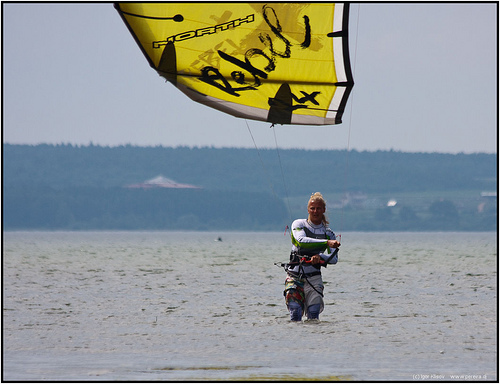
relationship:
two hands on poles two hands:
[285, 219, 336, 265] [286, 229, 342, 264]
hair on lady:
[307, 191, 331, 231] [277, 179, 345, 318]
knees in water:
[282, 300, 326, 321] [4, 220, 480, 381]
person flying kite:
[272, 186, 351, 321] [106, 6, 367, 127]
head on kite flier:
[305, 189, 331, 227] [283, 190, 339, 322]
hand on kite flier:
[327, 236, 341, 253] [283, 190, 339, 322]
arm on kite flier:
[289, 227, 341, 255] [283, 190, 339, 322]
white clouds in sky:
[401, 65, 459, 106] [4, 4, 481, 179]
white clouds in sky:
[401, 65, 459, 106] [0, 9, 483, 156]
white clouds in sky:
[401, 65, 459, 106] [0, 0, 474, 151]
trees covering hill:
[6, 139, 489, 232] [4, 134, 484, 228]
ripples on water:
[44, 265, 97, 289] [4, 220, 480, 381]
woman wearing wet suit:
[281, 183, 351, 325] [283, 219, 343, 316]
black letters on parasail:
[189, 10, 330, 109] [106, 1, 364, 131]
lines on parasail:
[233, 119, 305, 184] [106, 1, 364, 131]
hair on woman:
[301, 182, 337, 231] [281, 183, 351, 325]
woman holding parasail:
[281, 183, 351, 325] [106, 1, 364, 131]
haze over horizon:
[8, 8, 110, 84] [1, 127, 483, 165]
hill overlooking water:
[4, 134, 484, 228] [4, 220, 480, 381]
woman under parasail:
[281, 183, 351, 325] [106, 1, 364, 131]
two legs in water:
[279, 277, 322, 317] [4, 220, 480, 381]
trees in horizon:
[6, 139, 489, 232] [1, 127, 483, 165]